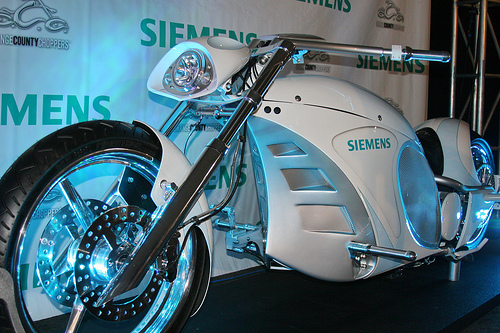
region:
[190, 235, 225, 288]
edge of a guard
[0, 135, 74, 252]
part of a wheel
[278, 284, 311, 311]
part of a floor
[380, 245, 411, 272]
part of a pedal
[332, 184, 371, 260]
edge of a bike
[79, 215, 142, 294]
part of a wheel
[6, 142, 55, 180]
edge of a wheel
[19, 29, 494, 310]
The bike is new.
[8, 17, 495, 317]
The bike is glossy.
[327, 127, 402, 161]
A logo is on the bike.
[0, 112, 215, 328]
The tire is black.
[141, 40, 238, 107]
The bike has a headlight.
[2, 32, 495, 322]
The bike is not being used.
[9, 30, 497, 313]
The bike is white.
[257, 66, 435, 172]
The bike has a white gas tank.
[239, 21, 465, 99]
Handlebars.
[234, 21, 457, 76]
The handlebars are gray.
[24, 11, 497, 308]
a motorcycle on display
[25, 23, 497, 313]
a white motorcycle on display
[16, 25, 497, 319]
a siemens motorcycle on display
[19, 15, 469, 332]
a white siemens motorcycle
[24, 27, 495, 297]
a motorcycle with head light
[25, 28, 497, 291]
a white bike on display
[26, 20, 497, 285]
a siemens bike on display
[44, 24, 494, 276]
a white siemens bike on display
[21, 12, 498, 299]
a motorcycle inside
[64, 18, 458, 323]
a bike is inside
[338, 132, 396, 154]
The word Siemens painted in green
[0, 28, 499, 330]
A brand new motorcycle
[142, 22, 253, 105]
A headlight on the front of a motorcycle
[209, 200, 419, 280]
The footrests on a motorcycle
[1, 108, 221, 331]
A clean black wheel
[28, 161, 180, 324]
Spokes on a a motorcycle wheel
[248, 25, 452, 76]
Shiny handlebars on a motorcycle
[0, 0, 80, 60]
An Orange County Choppers emblem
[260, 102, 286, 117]
Two small black circles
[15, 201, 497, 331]
A black platform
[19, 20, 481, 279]
white motorcycle on display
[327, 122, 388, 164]
siemens logo on bike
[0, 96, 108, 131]
siemens logo on wall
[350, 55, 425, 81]
siemens logo on wall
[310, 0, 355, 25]
siemens logo on wall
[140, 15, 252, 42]
siemens logo on wall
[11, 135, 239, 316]
front wheel of bike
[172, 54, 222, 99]
head light of bike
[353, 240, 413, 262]
foot stand of bike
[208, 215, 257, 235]
foot stand of bike